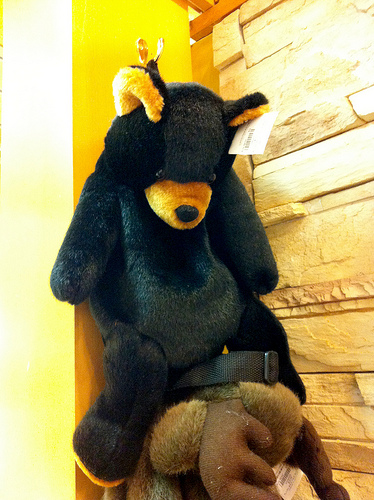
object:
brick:
[326, 300, 360, 396]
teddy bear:
[49, 66, 306, 485]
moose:
[118, 382, 350, 497]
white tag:
[245, 115, 274, 148]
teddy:
[41, 58, 291, 283]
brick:
[303, 127, 353, 196]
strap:
[167, 339, 292, 387]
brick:
[277, 191, 352, 332]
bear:
[49, 56, 308, 487]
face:
[128, 122, 232, 230]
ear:
[223, 91, 274, 127]